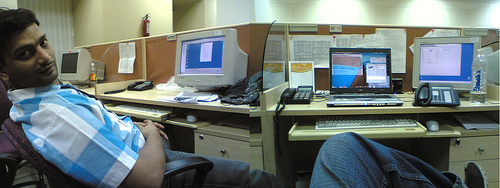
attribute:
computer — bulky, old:
[409, 31, 484, 98]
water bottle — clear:
[460, 42, 495, 122]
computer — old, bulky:
[164, 31, 255, 107]